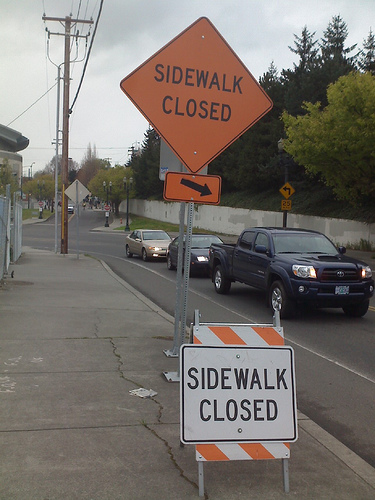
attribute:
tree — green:
[277, 58, 374, 213]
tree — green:
[281, 2, 355, 202]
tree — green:
[273, 16, 318, 191]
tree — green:
[246, 63, 280, 184]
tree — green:
[138, 119, 162, 193]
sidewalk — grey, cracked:
[0, 248, 373, 499]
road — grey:
[0, 206, 372, 465]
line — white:
[66, 243, 373, 391]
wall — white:
[115, 192, 371, 256]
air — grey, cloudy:
[1, 1, 374, 119]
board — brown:
[57, 183, 69, 243]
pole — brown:
[41, 12, 95, 253]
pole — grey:
[49, 60, 64, 254]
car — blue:
[205, 226, 371, 321]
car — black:
[164, 231, 230, 278]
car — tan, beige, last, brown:
[121, 225, 172, 262]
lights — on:
[289, 262, 321, 285]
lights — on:
[357, 263, 374, 284]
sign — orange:
[162, 169, 228, 207]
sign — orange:
[116, 14, 276, 175]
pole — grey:
[165, 200, 210, 355]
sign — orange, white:
[176, 305, 306, 499]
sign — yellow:
[276, 179, 299, 200]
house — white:
[0, 120, 34, 282]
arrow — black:
[178, 175, 213, 201]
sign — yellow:
[277, 196, 296, 213]